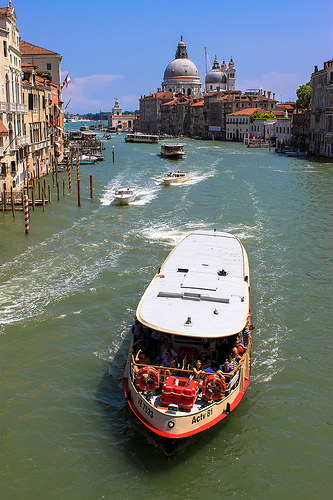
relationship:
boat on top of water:
[121, 224, 249, 458] [16, 120, 332, 493]